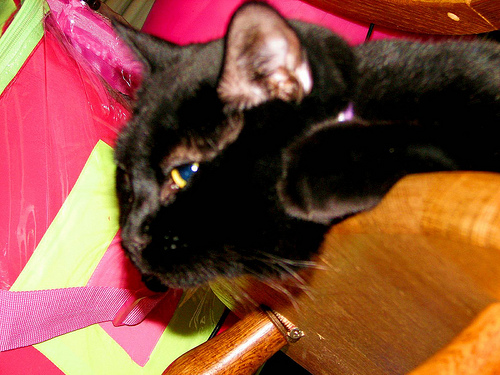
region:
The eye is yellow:
[153, 150, 213, 197]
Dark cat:
[70, 84, 354, 287]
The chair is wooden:
[309, 241, 491, 338]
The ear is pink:
[210, 7, 318, 130]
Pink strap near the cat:
[0, 258, 187, 369]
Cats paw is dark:
[270, 110, 435, 237]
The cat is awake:
[67, 98, 273, 253]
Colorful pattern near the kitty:
[20, 27, 151, 327]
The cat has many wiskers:
[170, 245, 406, 370]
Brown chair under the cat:
[290, 259, 445, 361]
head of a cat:
[72, 3, 387, 303]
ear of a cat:
[198, 7, 311, 119]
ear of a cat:
[85, 3, 188, 114]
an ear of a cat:
[67, 18, 190, 96]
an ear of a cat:
[185, 4, 322, 107]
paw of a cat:
[239, 123, 422, 223]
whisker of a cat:
[194, 233, 410, 303]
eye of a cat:
[159, 135, 221, 201]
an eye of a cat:
[162, 142, 207, 206]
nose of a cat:
[107, 206, 159, 273]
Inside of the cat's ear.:
[219, 6, 309, 103]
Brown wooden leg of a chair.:
[125, 307, 295, 374]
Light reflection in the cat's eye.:
[159, 157, 204, 189]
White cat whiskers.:
[188, 253, 350, 310]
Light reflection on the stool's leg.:
[171, 311, 292, 371]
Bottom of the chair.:
[225, 234, 494, 369]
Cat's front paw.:
[269, 116, 428, 226]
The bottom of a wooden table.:
[310, 0, 498, 42]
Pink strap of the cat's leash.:
[0, 269, 155, 354]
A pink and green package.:
[3, 3, 219, 362]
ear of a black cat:
[209, 0, 318, 118]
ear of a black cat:
[107, 14, 182, 74]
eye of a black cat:
[168, 152, 204, 194]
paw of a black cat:
[267, 110, 406, 236]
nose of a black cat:
[117, 225, 154, 255]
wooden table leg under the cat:
[155, 297, 296, 374]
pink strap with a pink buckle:
[0, 266, 167, 352]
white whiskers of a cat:
[170, 249, 344, 335]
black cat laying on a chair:
[78, 4, 495, 316]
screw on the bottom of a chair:
[283, 323, 305, 344]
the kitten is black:
[122, 37, 487, 318]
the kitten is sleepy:
[94, 34, 429, 295]